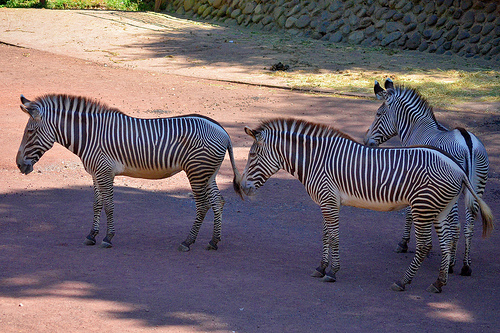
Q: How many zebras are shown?
A: 3.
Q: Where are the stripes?
A: On the zebras.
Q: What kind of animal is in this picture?
A: Zebra.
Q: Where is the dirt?
A: On the ground.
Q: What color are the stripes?
A: Black and white.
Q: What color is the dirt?
A: Reddish brown.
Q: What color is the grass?
A: Green.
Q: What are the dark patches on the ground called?
A: Shadows.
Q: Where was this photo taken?
A: Zoo.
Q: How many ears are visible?
A: Five.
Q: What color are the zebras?
A: Black and white.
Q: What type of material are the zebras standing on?
A: Dirt.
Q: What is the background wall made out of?
A: Stones.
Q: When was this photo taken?
A: Afternoon.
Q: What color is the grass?
A: Green.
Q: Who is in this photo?
A: No one.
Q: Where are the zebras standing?
A: In the tree's shadow.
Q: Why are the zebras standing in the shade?
A: To get out of the sun.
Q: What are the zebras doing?
A: Standing in the shade.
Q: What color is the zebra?
A: Black and white.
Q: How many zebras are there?
A: 3.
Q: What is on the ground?
A: Dirt.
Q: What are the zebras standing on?
A: Brown dirt.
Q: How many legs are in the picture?
A: 12.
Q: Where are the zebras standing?
A: In the shadow.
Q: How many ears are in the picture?
A: 6.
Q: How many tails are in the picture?
A: 3.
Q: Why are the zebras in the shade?
A: To stay cool.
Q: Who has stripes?
A: The zebra.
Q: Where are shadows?
A: On the ground.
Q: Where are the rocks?
A: On the slope on background.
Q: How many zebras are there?
A: 3.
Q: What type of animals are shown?
A: Zebras.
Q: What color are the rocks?
A: Grey.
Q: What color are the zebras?
A: Black and white.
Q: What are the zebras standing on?
A: Dirt.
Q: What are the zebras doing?
A: Standing.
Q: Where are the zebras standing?
A: In the shade.